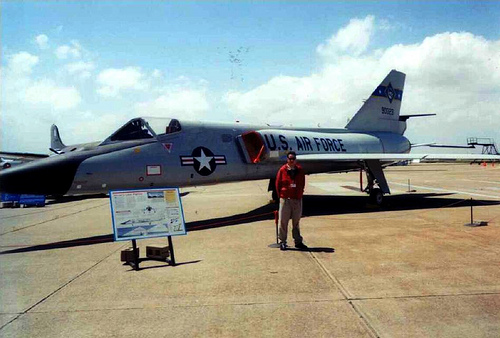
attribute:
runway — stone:
[335, 275, 430, 316]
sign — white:
[104, 179, 196, 240]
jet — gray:
[0, 67, 498, 201]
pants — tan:
[272, 194, 314, 252]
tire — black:
[365, 186, 386, 198]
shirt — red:
[271, 161, 308, 201]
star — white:
[193, 146, 216, 172]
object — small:
[459, 188, 495, 234]